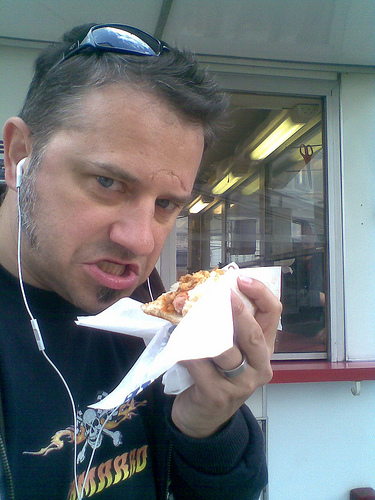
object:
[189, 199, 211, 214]
light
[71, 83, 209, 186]
forehead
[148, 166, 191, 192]
scar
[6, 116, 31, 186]
ear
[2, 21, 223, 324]
head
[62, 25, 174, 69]
glasses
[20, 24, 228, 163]
hair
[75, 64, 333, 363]
window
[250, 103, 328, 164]
light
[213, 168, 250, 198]
light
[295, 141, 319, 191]
scissors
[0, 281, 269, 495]
black shirt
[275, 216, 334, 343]
man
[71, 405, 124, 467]
crossbones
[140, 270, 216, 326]
hot dog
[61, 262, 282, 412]
napkin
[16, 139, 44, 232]
burn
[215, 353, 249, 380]
silver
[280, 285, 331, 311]
arm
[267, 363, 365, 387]
counter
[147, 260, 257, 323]
pizza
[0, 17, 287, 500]
man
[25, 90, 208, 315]
face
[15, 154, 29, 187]
earbud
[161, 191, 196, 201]
eyebrow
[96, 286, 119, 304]
beard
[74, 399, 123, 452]
skull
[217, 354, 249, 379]
ring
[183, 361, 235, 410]
finger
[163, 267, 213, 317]
meat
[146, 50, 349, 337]
shop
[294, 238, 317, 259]
expression